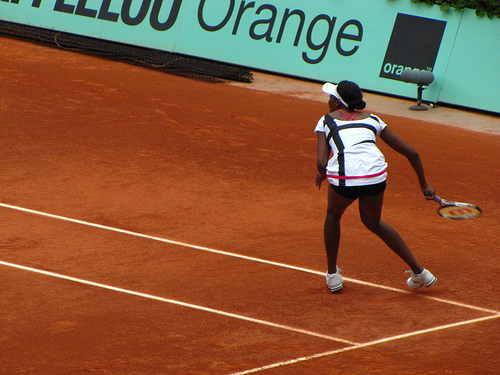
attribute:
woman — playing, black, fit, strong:
[300, 87, 466, 290]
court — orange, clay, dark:
[144, 122, 233, 200]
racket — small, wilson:
[425, 181, 478, 232]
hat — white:
[320, 79, 336, 102]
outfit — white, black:
[325, 124, 389, 176]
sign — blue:
[148, 13, 488, 91]